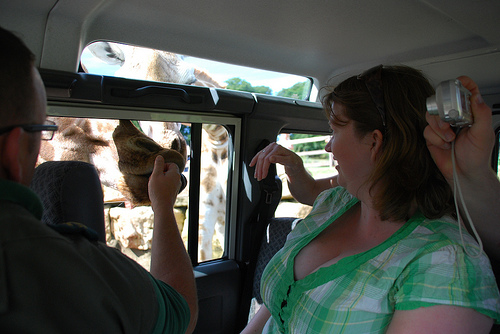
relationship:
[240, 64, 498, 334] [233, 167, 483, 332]
lady in shirt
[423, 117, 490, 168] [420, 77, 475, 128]
hand holding camera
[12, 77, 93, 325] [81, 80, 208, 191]
man petting giraffe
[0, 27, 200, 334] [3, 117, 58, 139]
man has on glasses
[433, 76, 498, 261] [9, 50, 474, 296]
person taking a picture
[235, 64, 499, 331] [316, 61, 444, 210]
lady with sunglasses on her head